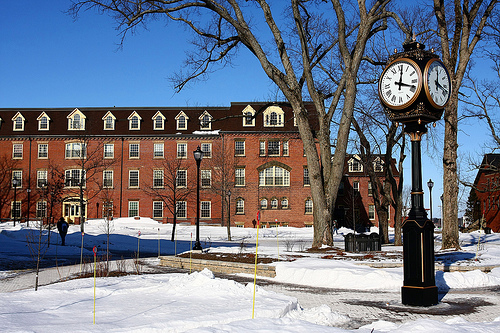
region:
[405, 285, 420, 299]
base of a pillar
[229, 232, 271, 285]
part of a stick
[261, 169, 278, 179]
part of a window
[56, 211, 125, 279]
part of a shade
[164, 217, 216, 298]
part of a pinter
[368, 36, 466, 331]
Large clock in front of building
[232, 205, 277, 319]
Stake sticking out of snow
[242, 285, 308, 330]
Snow drift by pole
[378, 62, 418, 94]
Black hands on the clock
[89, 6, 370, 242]
Large tree lost its leaves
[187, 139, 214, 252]
Street light beside sidewalk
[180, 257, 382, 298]
Sidewalk covered in snow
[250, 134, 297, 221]
Windows on side of building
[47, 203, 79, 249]
Person walking down sidewalk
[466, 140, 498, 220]
Red barn in background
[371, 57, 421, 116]
clock face on tower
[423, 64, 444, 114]
clock face on tower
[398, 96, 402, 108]
roman numeral on clock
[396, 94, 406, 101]
roman numeral on clock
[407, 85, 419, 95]
roman numeral on clock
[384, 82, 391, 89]
roman numeral on clock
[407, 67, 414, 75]
roman numeral on clock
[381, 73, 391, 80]
roman numeral on clock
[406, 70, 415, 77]
roman numeral on clock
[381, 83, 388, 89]
roman numeral on clock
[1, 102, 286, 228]
building in the background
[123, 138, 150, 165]
window on the building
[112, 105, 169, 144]
top of the building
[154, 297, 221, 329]
snow on the ground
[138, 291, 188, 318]
shadow of the pole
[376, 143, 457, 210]
pole under the clock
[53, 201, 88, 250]
person in the background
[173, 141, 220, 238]
pole on the ground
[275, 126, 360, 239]
tree in the snow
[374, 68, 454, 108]
two clocks on a pole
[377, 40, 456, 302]
a tall outdoor clock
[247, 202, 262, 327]
a yellow and red pole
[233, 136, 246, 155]
a window of a building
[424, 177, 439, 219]
a tall black lamp pole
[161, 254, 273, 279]
part of a stone wall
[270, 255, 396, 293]
a pile of white snow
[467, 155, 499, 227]
a short brown building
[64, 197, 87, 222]
a doorway of a building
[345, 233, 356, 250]
a black trashcan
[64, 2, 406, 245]
part of a tall tree with no leaves